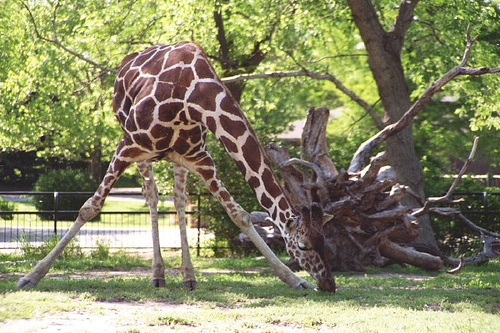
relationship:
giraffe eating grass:
[14, 40, 336, 295] [41, 269, 482, 332]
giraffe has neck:
[14, 40, 336, 295] [218, 129, 297, 213]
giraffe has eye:
[14, 40, 336, 295] [298, 237, 309, 254]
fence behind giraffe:
[1, 190, 224, 255] [14, 40, 336, 295]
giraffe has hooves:
[14, 40, 336, 295] [136, 271, 217, 296]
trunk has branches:
[287, 127, 422, 280] [359, 160, 500, 237]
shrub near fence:
[34, 162, 107, 223] [1, 190, 224, 255]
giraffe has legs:
[14, 40, 336, 295] [142, 179, 202, 287]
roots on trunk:
[296, 183, 379, 261] [287, 127, 422, 280]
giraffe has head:
[14, 40, 336, 295] [286, 222, 340, 308]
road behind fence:
[2, 217, 231, 252] [1, 190, 224, 255]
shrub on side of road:
[34, 162, 107, 223] [2, 217, 231, 252]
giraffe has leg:
[14, 40, 336, 295] [213, 178, 305, 297]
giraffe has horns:
[14, 40, 336, 295] [297, 203, 323, 229]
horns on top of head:
[297, 203, 323, 229] [286, 222, 340, 308]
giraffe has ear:
[14, 40, 336, 295] [282, 216, 299, 233]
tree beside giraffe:
[287, 20, 473, 269] [14, 40, 336, 295]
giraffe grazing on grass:
[14, 40, 341, 298] [41, 269, 482, 332]